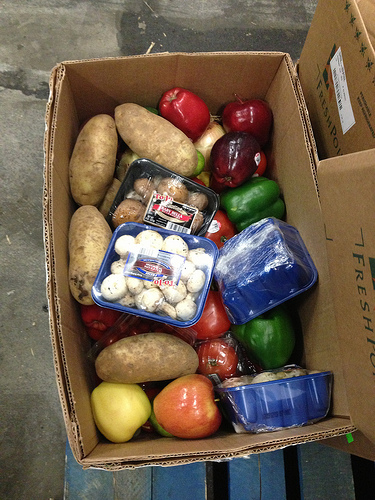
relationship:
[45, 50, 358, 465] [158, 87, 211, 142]
box contains apple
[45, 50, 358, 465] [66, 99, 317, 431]
box contains vegetables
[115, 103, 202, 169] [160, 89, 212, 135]
potato next to apple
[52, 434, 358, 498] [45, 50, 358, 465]
table holding box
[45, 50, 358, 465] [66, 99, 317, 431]
box has vegetables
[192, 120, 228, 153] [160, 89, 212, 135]
onion under apple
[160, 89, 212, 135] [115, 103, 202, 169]
apple beside potato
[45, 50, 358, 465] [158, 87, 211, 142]
box filled with apple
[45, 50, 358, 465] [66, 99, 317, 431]
box filled with vegetables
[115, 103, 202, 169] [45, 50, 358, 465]
potato inside box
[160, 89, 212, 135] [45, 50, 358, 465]
apple inside box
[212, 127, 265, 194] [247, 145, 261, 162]
apple has a sticker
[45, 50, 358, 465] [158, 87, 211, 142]
box of apple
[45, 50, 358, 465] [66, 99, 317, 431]
box full of vegetables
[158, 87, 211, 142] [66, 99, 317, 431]
apple are mixed with vegetables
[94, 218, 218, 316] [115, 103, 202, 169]
mushrooms are close to potato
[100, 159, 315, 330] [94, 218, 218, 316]
containers contain mushrooms